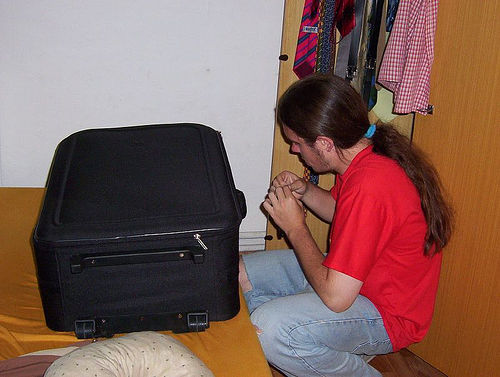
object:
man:
[237, 73, 458, 376]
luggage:
[30, 122, 248, 338]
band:
[361, 123, 378, 140]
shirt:
[320, 142, 442, 353]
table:
[0, 187, 272, 376]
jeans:
[238, 202, 393, 248]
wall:
[0, 0, 284, 192]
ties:
[292, 0, 318, 81]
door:
[407, 0, 499, 376]